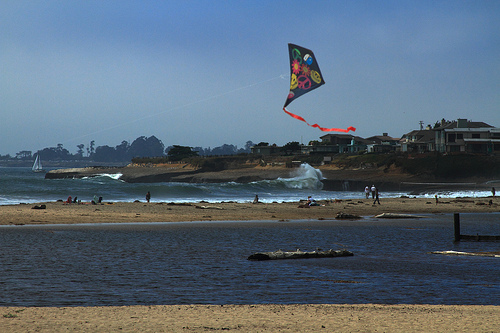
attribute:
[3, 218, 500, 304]
water — dark blue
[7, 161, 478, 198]
water — splashing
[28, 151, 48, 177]
sailboat — white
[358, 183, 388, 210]
people — walking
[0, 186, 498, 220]
shoreline — gold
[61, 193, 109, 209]
people — sitting, watchign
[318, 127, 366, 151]
house — distant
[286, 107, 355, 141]
ribbon — red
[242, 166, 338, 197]
waves — slamming, crashign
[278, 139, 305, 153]
tree — distant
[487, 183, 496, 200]
person — walking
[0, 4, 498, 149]
sky — blue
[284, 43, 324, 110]
kite — flying, mid-air, long, black